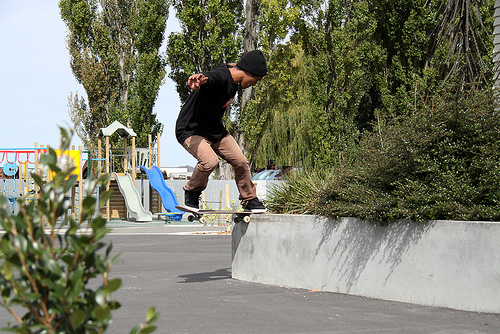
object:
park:
[0, 0, 500, 333]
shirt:
[175, 64, 242, 145]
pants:
[182, 134, 260, 202]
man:
[173, 47, 267, 214]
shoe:
[243, 195, 269, 216]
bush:
[312, 92, 500, 229]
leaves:
[315, 90, 328, 102]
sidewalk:
[0, 221, 500, 334]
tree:
[57, 1, 173, 181]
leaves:
[78, 27, 99, 43]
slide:
[140, 163, 188, 226]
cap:
[233, 49, 273, 79]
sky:
[2, 0, 352, 172]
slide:
[113, 168, 154, 224]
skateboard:
[175, 201, 269, 225]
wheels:
[243, 215, 252, 223]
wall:
[228, 211, 499, 314]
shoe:
[183, 186, 203, 213]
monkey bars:
[0, 147, 42, 178]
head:
[232, 46, 271, 91]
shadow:
[173, 266, 238, 284]